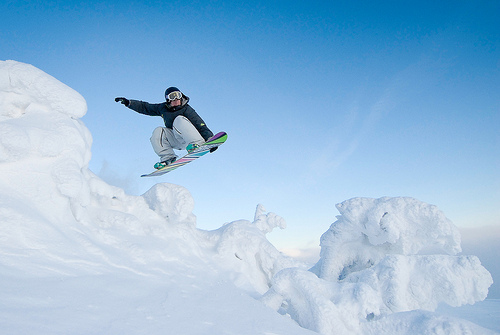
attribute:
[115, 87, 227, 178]
person — airborne, tricking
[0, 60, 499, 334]
snow — piled, white, winter, clumps, clumpy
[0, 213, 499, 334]
ground — snowy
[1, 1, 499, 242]
sky — clear, clean, day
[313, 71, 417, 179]
clouds — thin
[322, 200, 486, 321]
rocks — snowy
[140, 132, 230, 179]
snowboard — colored, blue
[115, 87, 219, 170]
man — airborne, tricking, snowboarding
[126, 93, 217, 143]
jacket — black, blue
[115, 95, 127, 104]
gloves — black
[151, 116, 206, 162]
pants — white